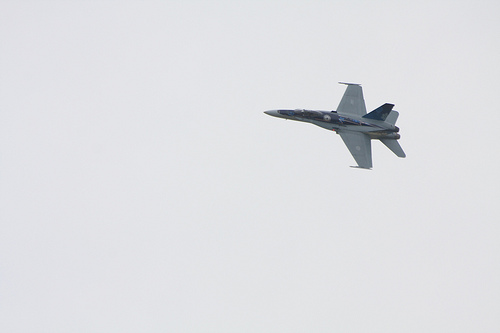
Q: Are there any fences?
A: No, there are no fences.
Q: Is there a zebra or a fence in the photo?
A: No, there are no fences or zebras.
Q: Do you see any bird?
A: No, there are no birds.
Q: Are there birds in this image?
A: No, there are no birds.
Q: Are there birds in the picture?
A: No, there are no birds.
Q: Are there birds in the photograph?
A: No, there are no birds.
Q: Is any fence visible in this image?
A: No, there are no fences.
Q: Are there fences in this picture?
A: No, there are no fences.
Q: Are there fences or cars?
A: No, there are no fences or cars.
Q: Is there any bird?
A: No, there are no birds.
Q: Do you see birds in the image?
A: No, there are no birds.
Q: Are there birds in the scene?
A: No, there are no birds.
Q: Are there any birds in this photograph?
A: No, there are no birds.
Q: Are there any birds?
A: No, there are no birds.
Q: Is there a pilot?
A: No, there are no pilots.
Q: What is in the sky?
A: The aircraft is in the sky.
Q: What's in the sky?
A: The aircraft is in the sky.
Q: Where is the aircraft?
A: The aircraft is in the sky.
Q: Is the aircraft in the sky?
A: Yes, the aircraft is in the sky.